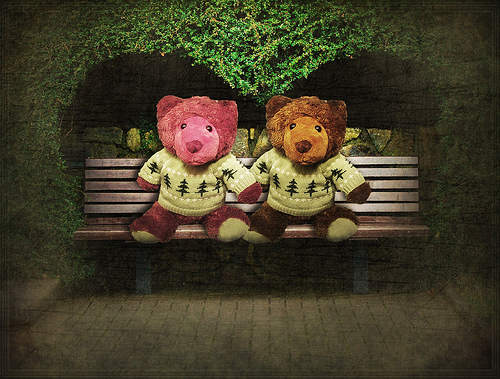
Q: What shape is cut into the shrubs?
A: Heart.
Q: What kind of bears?
A: Teddy bears.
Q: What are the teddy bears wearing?
A: Sweaters.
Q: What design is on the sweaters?
A: Trees.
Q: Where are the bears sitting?
A: Bench.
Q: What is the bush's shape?
A: Heart.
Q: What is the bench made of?
A: Wood.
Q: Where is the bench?
A: In a park.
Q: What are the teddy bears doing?
A: Holding hands.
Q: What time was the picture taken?
A: When it was dark.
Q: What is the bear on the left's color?
A: Pink.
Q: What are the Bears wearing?
A: Sweaters.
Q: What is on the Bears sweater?
A: Trees.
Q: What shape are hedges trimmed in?
A: Heart.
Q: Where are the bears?
A: On the bench.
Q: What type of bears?
A: Stuffed teddy bears.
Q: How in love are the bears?
A: Very much in love.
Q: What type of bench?
A: Wood.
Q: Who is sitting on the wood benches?
A: Bears.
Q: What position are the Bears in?
A: Seated.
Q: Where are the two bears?
A: Sitting on a wooden bench.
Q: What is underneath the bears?
A: A bench.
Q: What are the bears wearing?
A: Christmas sweaters.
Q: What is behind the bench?
A: A stone wall.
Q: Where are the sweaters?
A: On the bears.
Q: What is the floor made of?
A: Bricks.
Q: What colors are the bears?
A: Brown and pink.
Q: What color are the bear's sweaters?
A: Green.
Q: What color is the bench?
A: Brown.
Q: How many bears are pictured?
A: Two.